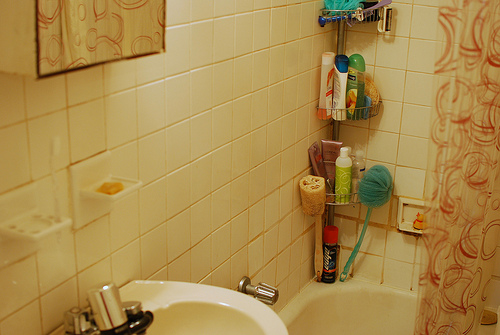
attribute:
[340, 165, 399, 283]
shower scrub — green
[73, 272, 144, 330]
faucet — silver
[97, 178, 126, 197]
soap — yellow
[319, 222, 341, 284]
bottle — black, red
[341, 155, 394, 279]
scrub — green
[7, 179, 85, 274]
toothbrush holder — ceramic, empty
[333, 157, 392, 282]
scrubber — green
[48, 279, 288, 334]
sink — white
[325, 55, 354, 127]
bottle — green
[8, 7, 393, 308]
wall — tiled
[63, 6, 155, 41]
mirror — metal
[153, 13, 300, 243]
wall — tiled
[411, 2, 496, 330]
curtain — clear, red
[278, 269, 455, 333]
bath tub — ceramic, white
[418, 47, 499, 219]
curtain — red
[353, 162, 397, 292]
poof — blue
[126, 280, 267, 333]
sink — ceramic, white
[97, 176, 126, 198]
bar soap — yellow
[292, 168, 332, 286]
loofah — leaning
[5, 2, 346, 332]
wall — tiled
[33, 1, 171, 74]
medicine cabinet — mirrored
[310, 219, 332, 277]
handle — wooden